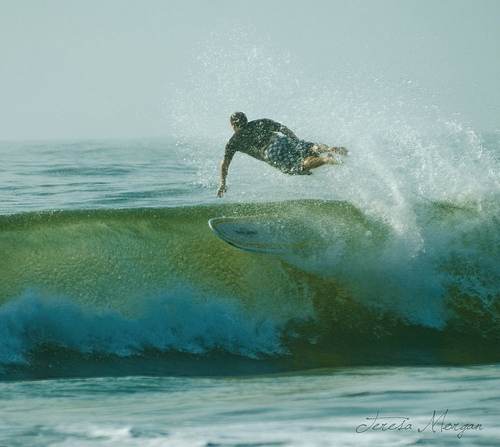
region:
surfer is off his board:
[207, 106, 351, 202]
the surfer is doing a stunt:
[202, 109, 352, 258]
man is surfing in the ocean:
[207, 106, 358, 278]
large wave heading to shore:
[2, 202, 491, 367]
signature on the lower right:
[338, 403, 490, 443]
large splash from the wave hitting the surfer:
[207, 71, 494, 327]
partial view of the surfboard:
[197, 205, 289, 262]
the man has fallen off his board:
[209, 94, 351, 196]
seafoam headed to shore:
[2, 366, 491, 442]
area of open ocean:
[1, 133, 491, 202]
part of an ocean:
[201, 220, 226, 274]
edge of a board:
[276, 249, 277, 252]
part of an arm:
[168, 260, 196, 282]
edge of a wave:
[222, 283, 254, 373]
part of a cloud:
[171, 328, 196, 367]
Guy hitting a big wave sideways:
[188, 102, 368, 200]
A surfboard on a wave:
[198, 211, 394, 261]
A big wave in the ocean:
[2, 204, 494, 362]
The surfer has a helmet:
[201, 101, 361, 199]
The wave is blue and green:
[0, 197, 475, 319]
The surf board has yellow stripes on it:
[192, 200, 412, 268]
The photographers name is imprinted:
[345, 404, 496, 439]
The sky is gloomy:
[0, 6, 467, 120]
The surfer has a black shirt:
[206, 104, 398, 210]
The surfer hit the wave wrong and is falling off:
[193, 92, 430, 268]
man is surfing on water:
[209, 103, 384, 235]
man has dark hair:
[217, 112, 249, 124]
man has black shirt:
[247, 115, 282, 158]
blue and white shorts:
[260, 121, 299, 178]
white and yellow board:
[195, 199, 350, 244]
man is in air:
[226, 75, 331, 221]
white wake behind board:
[332, 172, 492, 287]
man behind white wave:
[21, 251, 268, 388]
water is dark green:
[91, 193, 259, 295]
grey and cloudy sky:
[8, 55, 244, 95]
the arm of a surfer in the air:
[218, 143, 240, 188]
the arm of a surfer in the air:
[254, 118, 298, 138]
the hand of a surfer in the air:
[215, 185, 230, 194]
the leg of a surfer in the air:
[266, 143, 341, 170]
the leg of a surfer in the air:
[272, 134, 349, 158]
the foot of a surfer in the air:
[322, 152, 339, 167]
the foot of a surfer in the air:
[325, 143, 346, 156]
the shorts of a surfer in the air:
[261, 135, 316, 175]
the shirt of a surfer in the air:
[224, 118, 281, 158]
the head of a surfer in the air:
[228, 108, 245, 128]